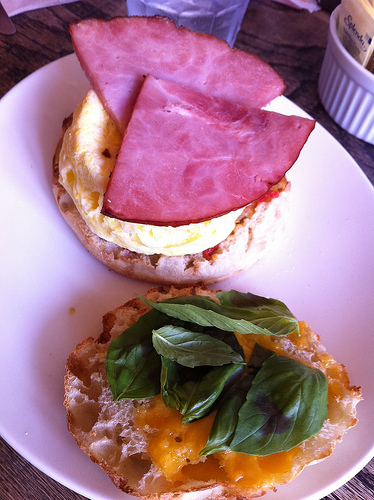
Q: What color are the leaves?
A: Green.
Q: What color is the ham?
A: Pink.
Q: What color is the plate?
A: White.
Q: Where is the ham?
A: To the upper-middle of the photo.